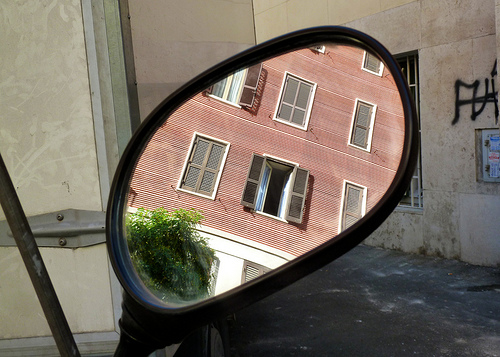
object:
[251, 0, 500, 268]
wall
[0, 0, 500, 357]
building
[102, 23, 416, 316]
mirror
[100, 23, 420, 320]
frame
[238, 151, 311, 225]
window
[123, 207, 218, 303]
tree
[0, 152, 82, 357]
rod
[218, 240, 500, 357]
ground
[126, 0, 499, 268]
structure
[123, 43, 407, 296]
building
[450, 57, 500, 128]
graffiti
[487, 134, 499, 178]
sign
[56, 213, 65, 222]
screw